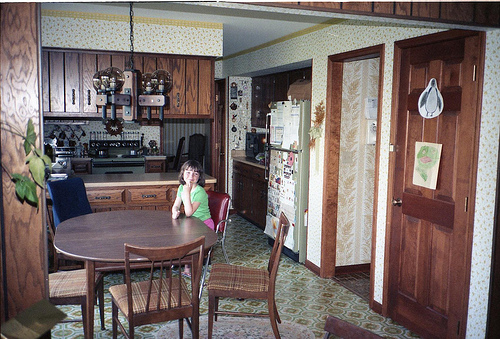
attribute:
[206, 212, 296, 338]
chair — brown, wooden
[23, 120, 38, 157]
leaves — peeping, green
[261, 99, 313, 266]
refrigerator — green, decorated, white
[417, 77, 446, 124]
drawing — of a penguin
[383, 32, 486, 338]
door — brown, wooden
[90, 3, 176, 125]
light fixture — hanging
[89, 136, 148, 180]
stove — silver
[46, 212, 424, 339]
flooring — yellow, patterned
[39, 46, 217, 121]
cabinets — wood, wooden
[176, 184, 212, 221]
top — green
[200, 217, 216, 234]
shorts — pink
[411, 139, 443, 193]
drawing — green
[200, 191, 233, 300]
chair — red-backed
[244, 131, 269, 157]
microwave — black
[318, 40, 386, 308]
doorframe — wooden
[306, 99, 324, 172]
things — hung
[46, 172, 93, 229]
chair — blue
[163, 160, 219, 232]
girl — little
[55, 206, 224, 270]
table — brown, round, wooden